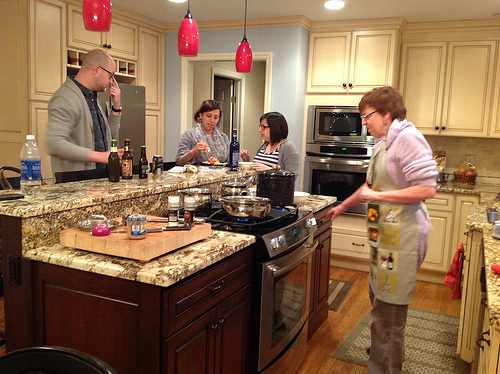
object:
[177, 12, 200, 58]
light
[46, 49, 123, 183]
man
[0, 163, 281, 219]
counters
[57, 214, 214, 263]
board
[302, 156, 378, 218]
stove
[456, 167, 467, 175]
fruits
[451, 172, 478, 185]
basket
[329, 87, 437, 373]
woman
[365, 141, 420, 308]
apron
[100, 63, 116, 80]
glasses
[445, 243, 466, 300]
towel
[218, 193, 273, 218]
pots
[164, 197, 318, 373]
stove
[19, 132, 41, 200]
bottle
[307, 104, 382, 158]
microwave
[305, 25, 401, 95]
cabinet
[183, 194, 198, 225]
spices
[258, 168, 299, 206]
pot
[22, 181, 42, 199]
water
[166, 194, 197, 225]
pair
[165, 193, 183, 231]
seasonings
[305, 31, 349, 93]
door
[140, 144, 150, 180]
beverage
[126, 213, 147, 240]
jar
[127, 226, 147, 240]
cheese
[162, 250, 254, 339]
drawer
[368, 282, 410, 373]
jeans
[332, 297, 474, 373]
rug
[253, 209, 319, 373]
oven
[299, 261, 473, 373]
floor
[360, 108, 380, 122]
glasses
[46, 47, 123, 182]
guy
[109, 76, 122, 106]
hand